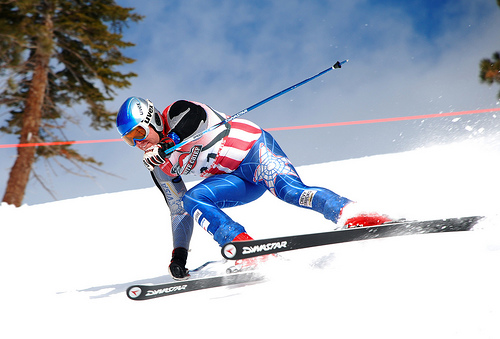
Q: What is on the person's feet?
A: Skis.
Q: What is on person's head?
A: Helmet.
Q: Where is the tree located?
A: On the left of the hill.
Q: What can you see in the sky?
A: Can see clouds.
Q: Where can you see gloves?
A: On the person's hands.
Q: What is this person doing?
A: Skiing.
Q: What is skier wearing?
A: A ski suit.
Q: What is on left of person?
A: A tall tree.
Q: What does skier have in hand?
A: Ski poles.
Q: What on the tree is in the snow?
A: Branches.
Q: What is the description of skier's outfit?
A: Red, white and blue.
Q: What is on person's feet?
A: Skis.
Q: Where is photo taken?
A: A snow covered hill.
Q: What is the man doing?
A: Skiing.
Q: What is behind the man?
A: A tree.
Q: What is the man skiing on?
A: Ice.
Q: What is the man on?
A: Skis.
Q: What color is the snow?
A: White.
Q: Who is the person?
A: A skier.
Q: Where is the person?
A: On skis.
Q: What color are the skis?
A: Black.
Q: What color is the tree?
A: Green.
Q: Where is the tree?
A: In snow.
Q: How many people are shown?
A: One.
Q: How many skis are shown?
A: Two.